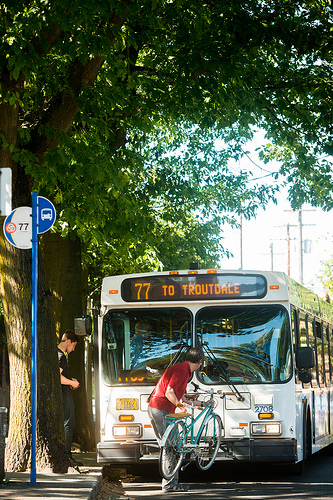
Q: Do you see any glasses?
A: No, there are no glasses.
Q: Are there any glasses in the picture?
A: No, there are no glasses.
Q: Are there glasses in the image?
A: No, there are no glasses.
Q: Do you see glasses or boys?
A: No, there are no glasses or boys.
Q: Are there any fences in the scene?
A: No, there are no fences.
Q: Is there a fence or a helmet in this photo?
A: No, there are no fences or helmets.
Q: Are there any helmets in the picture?
A: No, there are no helmets.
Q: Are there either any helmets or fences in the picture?
A: No, there are no helmets or fences.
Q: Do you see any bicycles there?
A: Yes, there is a bicycle.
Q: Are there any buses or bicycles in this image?
A: Yes, there is a bicycle.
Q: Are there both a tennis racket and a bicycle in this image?
A: No, there is a bicycle but no rackets.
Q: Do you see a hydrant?
A: No, there are no fire hydrants.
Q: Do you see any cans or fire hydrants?
A: No, there are no fire hydrants or cans.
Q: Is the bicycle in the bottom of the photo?
A: Yes, the bicycle is in the bottom of the image.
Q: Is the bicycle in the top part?
A: No, the bicycle is in the bottom of the image.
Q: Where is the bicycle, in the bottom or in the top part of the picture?
A: The bicycle is in the bottom of the image.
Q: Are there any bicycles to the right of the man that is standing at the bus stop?
A: Yes, there is a bicycle to the right of the man.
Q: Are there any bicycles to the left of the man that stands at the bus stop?
A: No, the bicycle is to the right of the man.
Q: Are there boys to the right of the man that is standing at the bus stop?
A: No, there is a bicycle to the right of the man.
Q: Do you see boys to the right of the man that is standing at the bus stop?
A: No, there is a bicycle to the right of the man.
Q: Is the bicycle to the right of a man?
A: Yes, the bicycle is to the right of a man.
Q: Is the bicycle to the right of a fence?
A: No, the bicycle is to the right of a man.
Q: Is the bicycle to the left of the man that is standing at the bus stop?
A: No, the bicycle is to the right of the man.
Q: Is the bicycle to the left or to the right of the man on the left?
A: The bicycle is to the right of the man.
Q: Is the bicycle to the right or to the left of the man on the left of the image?
A: The bicycle is to the right of the man.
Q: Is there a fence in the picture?
A: No, there are no fences.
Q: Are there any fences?
A: No, there are no fences.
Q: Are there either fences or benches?
A: No, there are no fences or benches.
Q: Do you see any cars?
A: No, there are no cars.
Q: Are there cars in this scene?
A: No, there are no cars.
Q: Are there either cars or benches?
A: No, there are no cars or benches.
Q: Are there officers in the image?
A: No, there are no officers.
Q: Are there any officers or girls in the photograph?
A: No, there are no officers or girls.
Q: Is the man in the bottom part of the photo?
A: Yes, the man is in the bottom of the image.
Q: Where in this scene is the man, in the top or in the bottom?
A: The man is in the bottom of the image.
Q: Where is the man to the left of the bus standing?
A: The man is standing at the bus stop.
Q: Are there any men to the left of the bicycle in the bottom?
A: Yes, there is a man to the left of the bicycle.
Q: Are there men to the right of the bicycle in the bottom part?
A: No, the man is to the left of the bicycle.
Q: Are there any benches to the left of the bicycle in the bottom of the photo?
A: No, there is a man to the left of the bicycle.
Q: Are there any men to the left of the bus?
A: Yes, there is a man to the left of the bus.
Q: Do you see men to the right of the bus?
A: No, the man is to the left of the bus.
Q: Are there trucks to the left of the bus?
A: No, there is a man to the left of the bus.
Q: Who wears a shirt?
A: The man wears a shirt.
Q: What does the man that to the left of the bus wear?
A: The man wears a shirt.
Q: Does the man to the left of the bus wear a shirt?
A: Yes, the man wears a shirt.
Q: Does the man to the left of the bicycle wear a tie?
A: No, the man wears a shirt.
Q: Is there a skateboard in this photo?
A: No, there are no skateboards.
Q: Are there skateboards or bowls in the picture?
A: No, there are no skateboards or bowls.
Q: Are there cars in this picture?
A: No, there are no cars.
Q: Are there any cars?
A: No, there are no cars.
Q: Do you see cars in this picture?
A: No, there are no cars.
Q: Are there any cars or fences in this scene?
A: No, there are no cars or fences.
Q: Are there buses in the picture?
A: Yes, there is a bus.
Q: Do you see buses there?
A: Yes, there is a bus.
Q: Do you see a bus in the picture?
A: Yes, there is a bus.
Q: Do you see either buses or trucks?
A: Yes, there is a bus.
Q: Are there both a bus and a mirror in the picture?
A: Yes, there are both a bus and a mirror.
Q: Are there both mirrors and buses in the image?
A: Yes, there are both a bus and a mirror.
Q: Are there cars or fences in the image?
A: No, there are no cars or fences.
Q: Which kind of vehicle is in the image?
A: The vehicle is a bus.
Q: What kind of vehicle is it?
A: The vehicle is a bus.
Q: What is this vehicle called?
A: This is a bus.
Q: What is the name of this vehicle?
A: This is a bus.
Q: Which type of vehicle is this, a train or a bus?
A: This is a bus.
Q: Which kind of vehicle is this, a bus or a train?
A: This is a bus.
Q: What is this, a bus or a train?
A: This is a bus.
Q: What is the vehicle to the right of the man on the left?
A: The vehicle is a bus.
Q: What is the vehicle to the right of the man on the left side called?
A: The vehicle is a bus.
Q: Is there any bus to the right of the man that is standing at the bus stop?
A: Yes, there is a bus to the right of the man.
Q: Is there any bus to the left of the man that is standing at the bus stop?
A: No, the bus is to the right of the man.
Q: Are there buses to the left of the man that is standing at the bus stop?
A: No, the bus is to the right of the man.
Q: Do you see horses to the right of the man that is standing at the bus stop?
A: No, there is a bus to the right of the man.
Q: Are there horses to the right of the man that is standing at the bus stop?
A: No, there is a bus to the right of the man.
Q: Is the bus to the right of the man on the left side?
A: Yes, the bus is to the right of the man.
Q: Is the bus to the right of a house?
A: No, the bus is to the right of the man.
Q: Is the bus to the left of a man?
A: No, the bus is to the right of a man.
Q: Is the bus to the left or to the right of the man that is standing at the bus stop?
A: The bus is to the right of the man.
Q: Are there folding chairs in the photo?
A: No, there are no folding chairs.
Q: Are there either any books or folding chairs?
A: No, there are no folding chairs or books.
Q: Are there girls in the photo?
A: No, there are no girls.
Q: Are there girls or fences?
A: No, there are no girls or fences.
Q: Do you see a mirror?
A: Yes, there is a mirror.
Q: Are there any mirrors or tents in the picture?
A: Yes, there is a mirror.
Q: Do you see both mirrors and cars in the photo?
A: No, there is a mirror but no cars.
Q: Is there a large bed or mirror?
A: Yes, there is a large mirror.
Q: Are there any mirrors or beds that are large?
A: Yes, the mirror is large.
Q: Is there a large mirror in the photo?
A: Yes, there is a large mirror.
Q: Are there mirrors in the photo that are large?
A: Yes, there is a mirror that is large.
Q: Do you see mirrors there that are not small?
A: Yes, there is a large mirror.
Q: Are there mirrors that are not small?
A: Yes, there is a large mirror.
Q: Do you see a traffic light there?
A: No, there are no traffic lights.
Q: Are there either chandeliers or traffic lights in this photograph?
A: No, there are no traffic lights or chandeliers.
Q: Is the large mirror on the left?
A: Yes, the mirror is on the left of the image.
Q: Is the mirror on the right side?
A: No, the mirror is on the left of the image.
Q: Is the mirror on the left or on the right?
A: The mirror is on the left of the image.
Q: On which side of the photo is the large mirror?
A: The mirror is on the left of the image.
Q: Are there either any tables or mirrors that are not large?
A: No, there is a mirror but it is large.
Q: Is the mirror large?
A: Yes, the mirror is large.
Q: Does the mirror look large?
A: Yes, the mirror is large.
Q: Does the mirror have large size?
A: Yes, the mirror is large.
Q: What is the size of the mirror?
A: The mirror is large.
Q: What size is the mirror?
A: The mirror is large.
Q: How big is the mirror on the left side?
A: The mirror is large.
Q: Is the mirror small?
A: No, the mirror is large.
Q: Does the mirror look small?
A: No, the mirror is large.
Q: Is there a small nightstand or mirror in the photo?
A: No, there is a mirror but it is large.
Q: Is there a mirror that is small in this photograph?
A: No, there is a mirror but it is large.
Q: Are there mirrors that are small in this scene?
A: No, there is a mirror but it is large.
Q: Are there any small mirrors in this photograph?
A: No, there is a mirror but it is large.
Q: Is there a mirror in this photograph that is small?
A: No, there is a mirror but it is large.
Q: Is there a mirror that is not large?
A: No, there is a mirror but it is large.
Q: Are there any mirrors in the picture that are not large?
A: No, there is a mirror but it is large.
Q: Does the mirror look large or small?
A: The mirror is large.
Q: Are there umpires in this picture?
A: No, there are no umpires.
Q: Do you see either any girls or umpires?
A: No, there are no umpires or girls.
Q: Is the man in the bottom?
A: Yes, the man is in the bottom of the image.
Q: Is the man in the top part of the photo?
A: No, the man is in the bottom of the image.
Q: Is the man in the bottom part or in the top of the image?
A: The man is in the bottom of the image.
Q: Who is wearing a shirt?
A: The man is wearing a shirt.